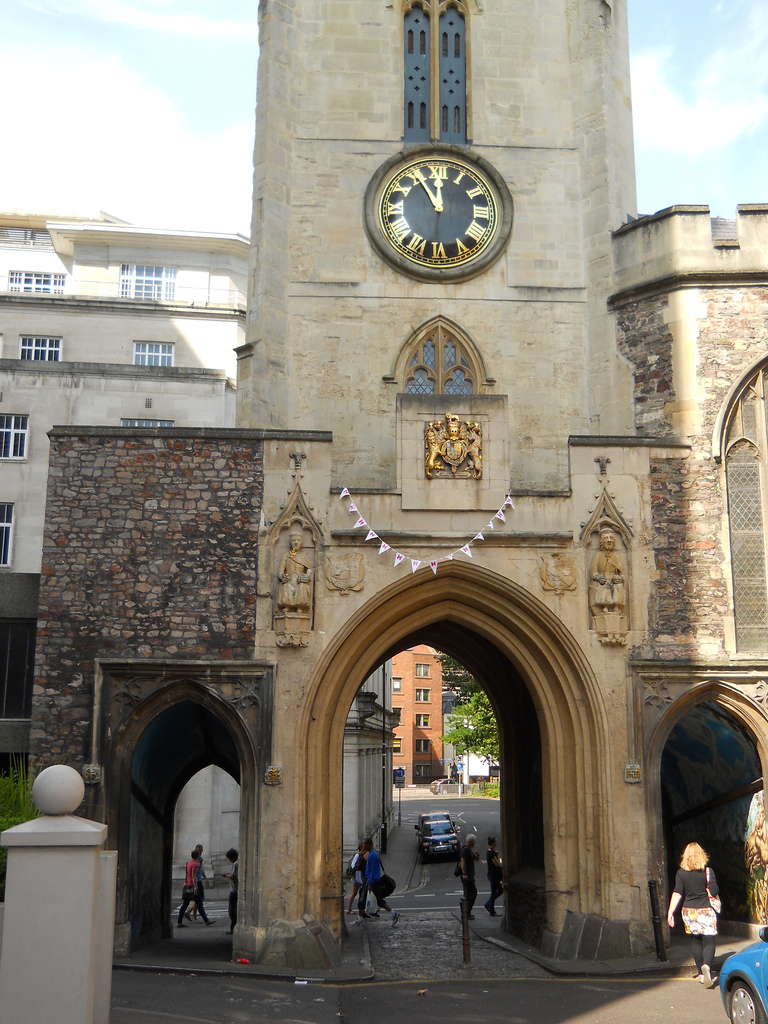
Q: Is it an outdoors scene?
A: Yes, it is outdoors.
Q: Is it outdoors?
A: Yes, it is outdoors.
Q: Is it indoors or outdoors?
A: It is outdoors.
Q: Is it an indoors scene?
A: No, it is outdoors.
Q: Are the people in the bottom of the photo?
A: Yes, the people are in the bottom of the image.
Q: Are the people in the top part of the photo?
A: No, the people are in the bottom of the image.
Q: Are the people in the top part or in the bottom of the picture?
A: The people are in the bottom of the image.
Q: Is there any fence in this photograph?
A: No, there are no fences.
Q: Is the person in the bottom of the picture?
A: Yes, the person is in the bottom of the image.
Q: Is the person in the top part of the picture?
A: No, the person is in the bottom of the image.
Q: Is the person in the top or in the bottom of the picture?
A: The person is in the bottom of the image.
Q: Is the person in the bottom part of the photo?
A: Yes, the person is in the bottom of the image.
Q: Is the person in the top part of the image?
A: No, the person is in the bottom of the image.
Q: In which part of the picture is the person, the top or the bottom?
A: The person is in the bottom of the image.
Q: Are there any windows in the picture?
A: Yes, there is a window.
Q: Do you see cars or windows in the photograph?
A: Yes, there is a window.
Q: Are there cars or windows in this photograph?
A: Yes, there is a window.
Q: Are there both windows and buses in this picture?
A: No, there is a window but no buses.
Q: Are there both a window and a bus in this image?
A: No, there is a window but no buses.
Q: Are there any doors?
A: No, there are no doors.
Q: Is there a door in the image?
A: No, there are no doors.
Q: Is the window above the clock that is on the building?
A: Yes, the window is above the clock.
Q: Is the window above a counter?
A: No, the window is above the clock.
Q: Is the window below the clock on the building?
A: No, the window is above the clock.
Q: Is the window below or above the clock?
A: The window is above the clock.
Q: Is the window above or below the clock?
A: The window is above the clock.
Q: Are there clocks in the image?
A: Yes, there is a clock.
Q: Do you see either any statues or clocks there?
A: Yes, there is a clock.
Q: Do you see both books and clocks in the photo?
A: No, there is a clock but no books.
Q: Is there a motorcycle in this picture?
A: No, there are no motorcycles.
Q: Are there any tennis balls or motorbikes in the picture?
A: No, there are no motorbikes or tennis balls.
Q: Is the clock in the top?
A: Yes, the clock is in the top of the image.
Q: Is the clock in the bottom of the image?
A: No, the clock is in the top of the image.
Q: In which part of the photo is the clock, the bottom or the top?
A: The clock is in the top of the image.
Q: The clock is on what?
A: The clock is on the building.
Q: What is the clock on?
A: The clock is on the building.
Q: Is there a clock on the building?
A: Yes, there is a clock on the building.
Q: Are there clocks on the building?
A: Yes, there is a clock on the building.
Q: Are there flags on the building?
A: No, there is a clock on the building.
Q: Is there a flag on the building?
A: No, there is a clock on the building.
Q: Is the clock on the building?
A: Yes, the clock is on the building.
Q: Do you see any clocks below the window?
A: Yes, there is a clock below the window.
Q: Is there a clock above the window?
A: No, the clock is below the window.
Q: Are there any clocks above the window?
A: No, the clock is below the window.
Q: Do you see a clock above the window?
A: No, the clock is below the window.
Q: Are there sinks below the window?
A: No, there is a clock below the window.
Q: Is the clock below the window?
A: Yes, the clock is below the window.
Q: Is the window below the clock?
A: No, the clock is below the window.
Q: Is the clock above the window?
A: No, the clock is below the window.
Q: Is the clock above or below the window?
A: The clock is below the window.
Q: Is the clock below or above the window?
A: The clock is below the window.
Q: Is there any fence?
A: No, there are no fences.